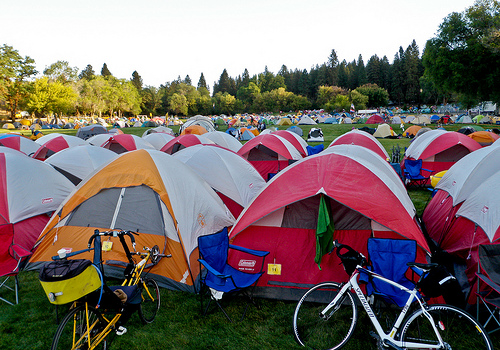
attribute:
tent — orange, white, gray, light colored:
[25, 145, 240, 296]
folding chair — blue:
[192, 228, 270, 330]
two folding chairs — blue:
[190, 225, 435, 325]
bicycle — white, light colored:
[286, 240, 493, 348]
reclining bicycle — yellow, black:
[49, 226, 175, 350]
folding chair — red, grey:
[1, 223, 21, 309]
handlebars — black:
[328, 239, 371, 275]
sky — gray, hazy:
[3, 1, 487, 92]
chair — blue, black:
[401, 154, 434, 192]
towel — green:
[311, 187, 339, 270]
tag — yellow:
[263, 254, 288, 280]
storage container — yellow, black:
[41, 255, 106, 309]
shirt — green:
[309, 187, 337, 268]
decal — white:
[236, 255, 259, 274]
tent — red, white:
[229, 147, 431, 304]